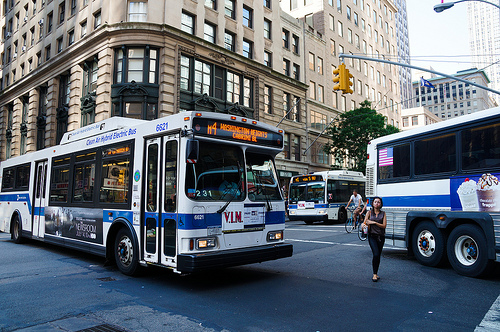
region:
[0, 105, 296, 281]
a white and blue bus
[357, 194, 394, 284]
a woman in a sleeveless top crossing the street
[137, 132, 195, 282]
the front doors of a bus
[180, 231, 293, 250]
headlights of a bus turned on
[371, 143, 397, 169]
the image of the american flag on a bus window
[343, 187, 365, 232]
a man on a bicycle riding on a city street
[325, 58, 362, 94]
an overhead stoplight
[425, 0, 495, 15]
a streetlight on top of a pole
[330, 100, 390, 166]
a tree with green leaves next to a street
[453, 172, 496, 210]
an advertisement on the side of a bus for ice cream based drinks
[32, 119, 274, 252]
blue and white transit bus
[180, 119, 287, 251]
blue and white transit bus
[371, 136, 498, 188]
blue and white transit bus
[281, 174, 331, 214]
blue and white transit bus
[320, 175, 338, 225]
blue and white transit bus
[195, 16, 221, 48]
black window in brown building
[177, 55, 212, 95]
black window in brown building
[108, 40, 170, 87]
black window in brown building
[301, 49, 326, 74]
black window in brown building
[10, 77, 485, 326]
busy intersection with three busses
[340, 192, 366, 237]
person riding a bike in road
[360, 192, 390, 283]
lady walking in front of bus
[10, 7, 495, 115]
several buildings in a row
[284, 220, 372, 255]
lines marking crosswalk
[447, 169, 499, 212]
photo of beverages on side of bus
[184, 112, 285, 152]
illuminated digital sign on front of bus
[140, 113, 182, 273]
bus door with 6621 above it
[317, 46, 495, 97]
traffic light suspended from metal pole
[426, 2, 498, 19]
streetlight on pole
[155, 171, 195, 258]
edge of a bus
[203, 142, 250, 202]
part of a window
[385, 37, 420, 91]
part of a metal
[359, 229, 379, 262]
part of a jeans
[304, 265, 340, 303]
part of a road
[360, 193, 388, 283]
Woman crossing in front of bus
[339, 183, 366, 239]
Man in gray shirt riding bicycle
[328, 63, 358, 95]
Yellow traffic light attached to gray pole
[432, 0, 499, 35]
Light post above traffic light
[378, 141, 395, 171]
American flag printed on bus window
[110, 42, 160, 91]
Large black window on building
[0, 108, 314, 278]
Large blue and white bus near another bus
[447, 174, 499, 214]
Beverage advertisement on bus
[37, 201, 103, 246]
TV show advertisement on bus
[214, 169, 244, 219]
Large black windshield wiper on window of bus